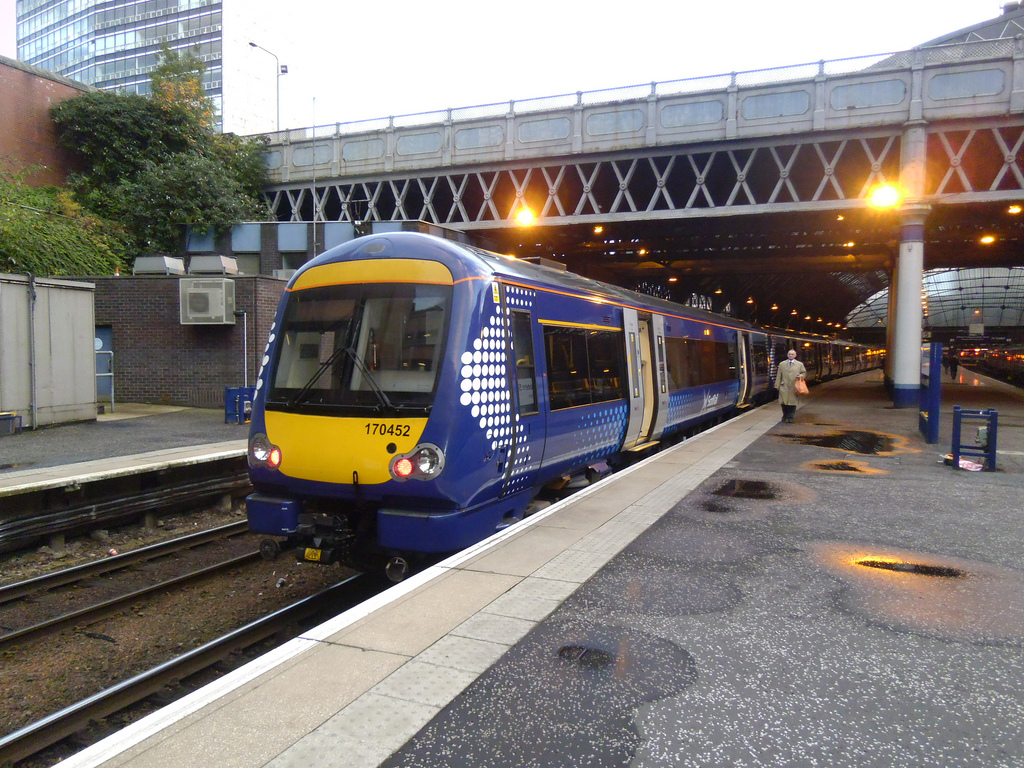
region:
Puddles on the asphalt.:
[720, 383, 968, 614]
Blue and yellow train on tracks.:
[0, 226, 861, 743]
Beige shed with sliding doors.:
[9, 273, 101, 428]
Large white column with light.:
[866, 120, 934, 409]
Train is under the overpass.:
[204, 43, 1017, 528]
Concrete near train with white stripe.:
[33, 402, 783, 764]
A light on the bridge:
[866, 177, 902, 220]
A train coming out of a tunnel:
[231, 225, 881, 567]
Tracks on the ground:
[1, 504, 379, 758]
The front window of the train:
[277, 276, 432, 414]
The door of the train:
[629, 314, 662, 447]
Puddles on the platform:
[712, 411, 954, 608]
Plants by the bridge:
[76, 67, 273, 251]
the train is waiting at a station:
[230, 218, 923, 517]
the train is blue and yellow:
[227, 236, 521, 537]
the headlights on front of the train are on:
[246, 432, 449, 506]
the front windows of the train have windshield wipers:
[271, 285, 449, 406]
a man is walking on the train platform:
[768, 337, 816, 439]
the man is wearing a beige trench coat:
[770, 341, 812, 437]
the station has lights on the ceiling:
[517, 239, 1023, 337]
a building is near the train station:
[21, 6, 552, 621]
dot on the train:
[446, 354, 476, 364]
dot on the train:
[485, 315, 511, 328]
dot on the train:
[484, 439, 504, 459]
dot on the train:
[490, 373, 510, 386]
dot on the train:
[263, 325, 279, 349]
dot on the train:
[248, 382, 264, 393]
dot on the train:
[504, 464, 517, 469]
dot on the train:
[484, 408, 497, 435]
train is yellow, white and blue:
[222, 213, 660, 607]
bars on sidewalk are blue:
[936, 393, 1022, 491]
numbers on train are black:
[350, 405, 424, 470]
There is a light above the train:
[485, 197, 558, 243]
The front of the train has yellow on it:
[255, 262, 461, 496]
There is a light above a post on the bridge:
[855, 169, 920, 223]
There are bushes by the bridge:
[0, 90, 273, 288]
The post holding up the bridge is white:
[887, 208, 944, 415]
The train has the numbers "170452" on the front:
[356, 415, 418, 445]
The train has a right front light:
[229, 429, 287, 483]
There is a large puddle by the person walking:
[777, 420, 911, 462]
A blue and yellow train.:
[244, 229, 890, 583]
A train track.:
[0, 362, 1019, 765]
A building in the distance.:
[14, 0, 221, 137]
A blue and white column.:
[892, 201, 924, 408]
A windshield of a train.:
[266, 288, 456, 409]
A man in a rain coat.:
[771, 345, 809, 423]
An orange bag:
[794, 377, 810, 397]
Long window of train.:
[539, 319, 631, 411]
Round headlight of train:
[390, 447, 442, 480]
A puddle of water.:
[714, 476, 779, 502]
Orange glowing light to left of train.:
[514, 205, 537, 229]